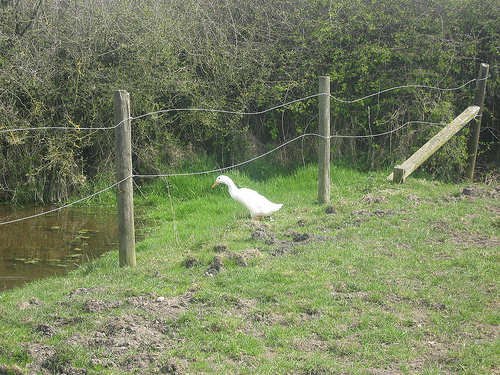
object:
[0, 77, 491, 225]
barbed wire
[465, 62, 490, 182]
post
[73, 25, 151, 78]
limbs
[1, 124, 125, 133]
wire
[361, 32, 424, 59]
leaves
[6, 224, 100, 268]
leaves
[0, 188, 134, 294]
dirty water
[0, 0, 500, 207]
trees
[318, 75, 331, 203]
pole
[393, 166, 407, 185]
pole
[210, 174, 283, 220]
duck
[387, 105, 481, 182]
wood piece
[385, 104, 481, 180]
fallen board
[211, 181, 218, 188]
beak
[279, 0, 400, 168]
limbs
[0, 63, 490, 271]
fence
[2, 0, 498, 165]
branches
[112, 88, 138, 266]
fence pole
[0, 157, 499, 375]
grass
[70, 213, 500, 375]
patch